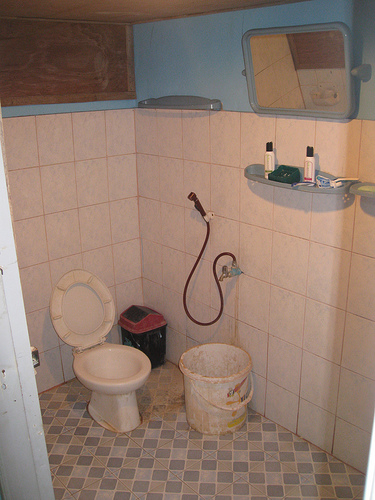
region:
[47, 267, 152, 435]
Toilet with seat up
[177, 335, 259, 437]
Dirty bucket against wall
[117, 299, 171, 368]
Garbage bin in the corner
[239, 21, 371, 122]
Mirror on wall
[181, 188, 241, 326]
Hose attaches to faucet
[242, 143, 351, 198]
Toiletries on shelf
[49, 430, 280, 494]
Tiled blue and tan floor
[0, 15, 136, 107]
Wooden panel in wall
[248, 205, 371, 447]
White tiled wall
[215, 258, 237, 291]
Faucet attached to wall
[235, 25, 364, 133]
the mirror on the wall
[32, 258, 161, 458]
the toilet bowl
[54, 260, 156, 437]
the toilet seat is up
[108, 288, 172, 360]
the waste bin in the corner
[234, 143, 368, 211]
the toiletries on the shelf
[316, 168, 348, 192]
the toothpaste on the shelf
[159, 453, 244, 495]
the floor is tiled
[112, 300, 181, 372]
the waste bin is red and black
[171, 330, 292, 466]
the dirty bucket under the faucet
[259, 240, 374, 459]
the tiles on the wall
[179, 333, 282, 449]
Dirty bucket in the bathroom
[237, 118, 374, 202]
Plastic shelf for toiletries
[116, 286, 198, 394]
Black and red garbage bin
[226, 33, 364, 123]
Mirror with blue trim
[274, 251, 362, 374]
White tiles on the wall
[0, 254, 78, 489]
White bathroom door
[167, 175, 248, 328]
Water fountain for toilet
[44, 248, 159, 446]
White commode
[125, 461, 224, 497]
Grey and white tiles on the floor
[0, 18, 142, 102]
Wooden plank to close window opening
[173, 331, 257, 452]
a white plastic bucket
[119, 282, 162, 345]
a red and black garbage can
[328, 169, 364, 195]
a razor on a plastic shelf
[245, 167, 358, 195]
a blue plastic shelf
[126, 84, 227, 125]
a towel rod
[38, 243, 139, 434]
a white toilet with the lid up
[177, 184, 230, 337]
a red hose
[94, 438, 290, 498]
a tile floor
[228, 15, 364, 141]
a blue mirror on the wall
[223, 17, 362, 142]
a blue mirror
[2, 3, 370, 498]
a disgusting bathroom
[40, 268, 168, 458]
a dirty toilet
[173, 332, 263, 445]
a bucket being used as a shower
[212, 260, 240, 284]
a water faucet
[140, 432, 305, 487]
checkered bathroom tile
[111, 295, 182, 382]
filthy bathroom trashcan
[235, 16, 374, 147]
unusual bathroom mirror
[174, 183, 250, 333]
ghetto bathroom shower on a dirty wall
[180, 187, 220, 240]
red shower head in a disgusting bathroom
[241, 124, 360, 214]
disgusting bathroom toiletries